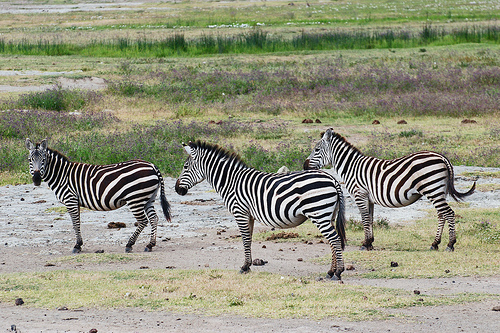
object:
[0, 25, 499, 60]
grass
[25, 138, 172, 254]
zebra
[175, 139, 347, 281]
zebra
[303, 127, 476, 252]
zebra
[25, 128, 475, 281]
zebras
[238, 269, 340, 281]
hooves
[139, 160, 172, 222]
tail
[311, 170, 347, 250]
tail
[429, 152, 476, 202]
tail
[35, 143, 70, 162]
mane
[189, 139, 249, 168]
mane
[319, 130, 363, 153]
mane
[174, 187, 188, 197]
mouth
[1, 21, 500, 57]
reeds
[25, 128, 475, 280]
line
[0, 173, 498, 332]
dirt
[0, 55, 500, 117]
some grass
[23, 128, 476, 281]
clumps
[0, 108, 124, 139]
flowers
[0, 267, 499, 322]
grass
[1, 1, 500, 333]
field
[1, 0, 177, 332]
right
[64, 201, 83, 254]
front legs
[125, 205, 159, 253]
back legs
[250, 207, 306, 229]
belly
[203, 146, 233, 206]
neck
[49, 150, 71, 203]
neck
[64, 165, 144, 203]
stripes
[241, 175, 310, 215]
stripes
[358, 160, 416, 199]
stripes